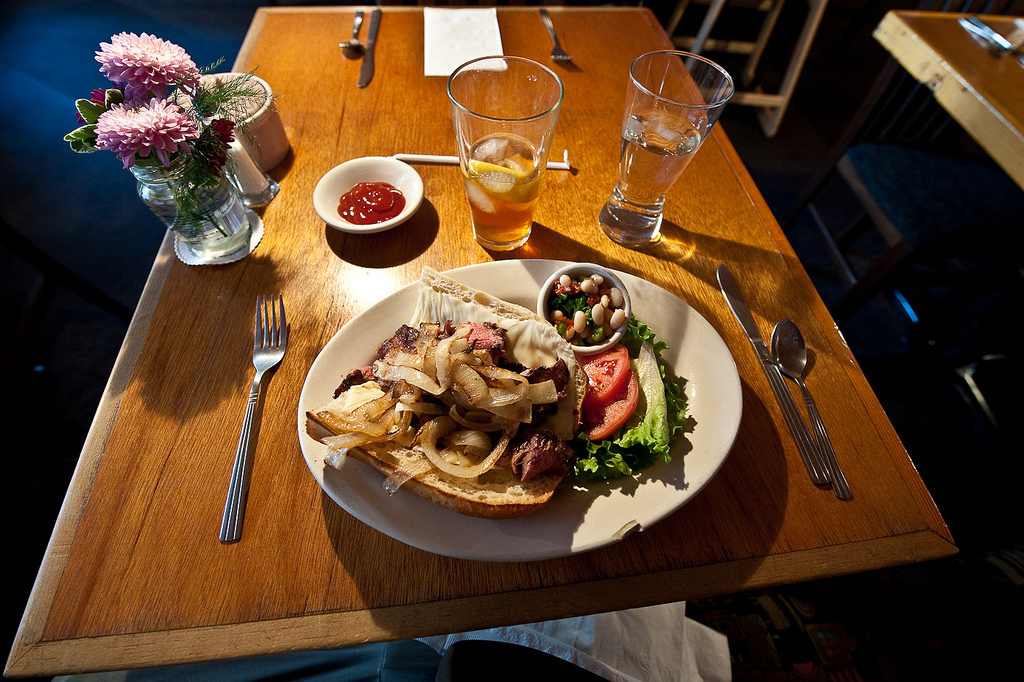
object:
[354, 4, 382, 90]
knife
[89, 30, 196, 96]
flowers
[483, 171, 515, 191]
ice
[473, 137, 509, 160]
ice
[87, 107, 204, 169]
flowers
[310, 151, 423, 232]
bowl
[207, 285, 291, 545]
fork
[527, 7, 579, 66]
fork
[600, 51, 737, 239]
glass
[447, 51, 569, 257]
glass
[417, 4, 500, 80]
napkin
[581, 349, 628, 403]
tomatoes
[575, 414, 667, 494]
lettuce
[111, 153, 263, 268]
vase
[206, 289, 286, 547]
fork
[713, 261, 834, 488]
knife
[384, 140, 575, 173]
drinkingstraw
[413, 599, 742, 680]
napkin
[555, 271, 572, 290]
food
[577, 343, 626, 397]
food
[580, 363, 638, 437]
food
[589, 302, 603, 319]
food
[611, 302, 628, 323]
food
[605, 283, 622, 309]
food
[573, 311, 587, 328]
food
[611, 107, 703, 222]
ice water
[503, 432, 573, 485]
food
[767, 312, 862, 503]
spoon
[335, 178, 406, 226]
ketchup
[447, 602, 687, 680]
lap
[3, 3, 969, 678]
table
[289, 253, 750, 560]
plate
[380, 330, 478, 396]
food